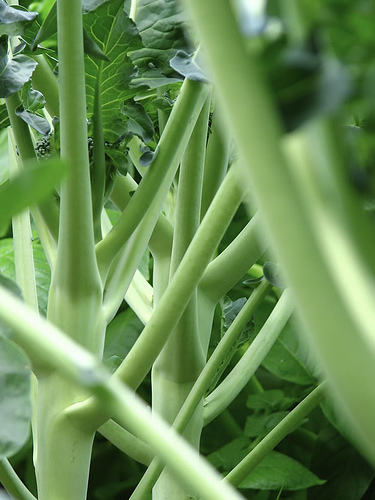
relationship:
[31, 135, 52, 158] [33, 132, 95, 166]
flower of broccoli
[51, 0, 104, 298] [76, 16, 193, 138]
stem on plant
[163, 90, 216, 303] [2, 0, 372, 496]
stalk on plant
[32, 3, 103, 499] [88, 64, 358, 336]
stem of a plant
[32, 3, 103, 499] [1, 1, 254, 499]
stem of a plant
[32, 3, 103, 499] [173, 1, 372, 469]
stem of a plant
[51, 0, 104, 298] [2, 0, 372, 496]
stem of a plant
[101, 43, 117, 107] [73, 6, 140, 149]
veins of a leaf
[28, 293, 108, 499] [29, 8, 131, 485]
stem of broccoli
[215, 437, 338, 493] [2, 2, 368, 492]
leaf of broccoli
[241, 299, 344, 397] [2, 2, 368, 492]
leaf of broccoli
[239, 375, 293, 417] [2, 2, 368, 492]
leaf of broccoli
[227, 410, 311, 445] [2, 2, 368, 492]
leaf of broccoli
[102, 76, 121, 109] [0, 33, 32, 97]
vein of leaf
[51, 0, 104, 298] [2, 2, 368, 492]
stem of broccoli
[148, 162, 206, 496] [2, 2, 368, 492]
stem of broccoli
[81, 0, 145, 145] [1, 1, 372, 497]
leaf of tree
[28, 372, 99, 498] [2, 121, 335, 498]
stem of tree